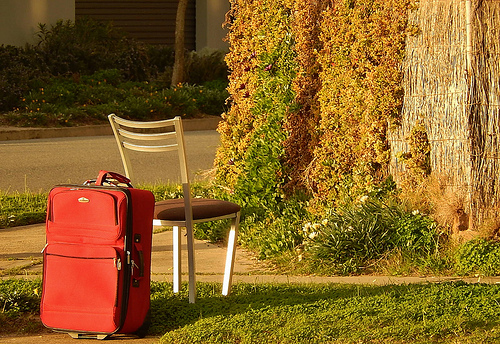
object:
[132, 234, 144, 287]
handle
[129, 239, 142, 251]
red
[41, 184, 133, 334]
zipper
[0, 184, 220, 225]
grass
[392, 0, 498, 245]
trunk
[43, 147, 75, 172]
pavement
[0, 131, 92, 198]
street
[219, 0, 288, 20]
leaves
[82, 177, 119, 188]
handle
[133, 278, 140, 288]
button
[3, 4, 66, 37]
wall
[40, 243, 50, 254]
silver zipper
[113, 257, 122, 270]
silver zipper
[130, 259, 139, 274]
silver zipper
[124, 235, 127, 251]
silver zipper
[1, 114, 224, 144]
curb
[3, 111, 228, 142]
sidewalk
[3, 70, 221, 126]
grass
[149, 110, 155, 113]
flower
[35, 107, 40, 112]
flower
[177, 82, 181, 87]
flower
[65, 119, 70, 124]
flower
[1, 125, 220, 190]
road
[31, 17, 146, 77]
bush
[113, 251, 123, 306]
zipper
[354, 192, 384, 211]
flowers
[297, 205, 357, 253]
flowers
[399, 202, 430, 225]
flowers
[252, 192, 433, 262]
grass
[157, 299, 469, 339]
ground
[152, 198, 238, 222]
cushion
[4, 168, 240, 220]
curb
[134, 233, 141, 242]
button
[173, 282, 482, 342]
grass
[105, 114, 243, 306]
chair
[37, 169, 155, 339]
suitcase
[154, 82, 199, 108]
flowers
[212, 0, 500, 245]
tree